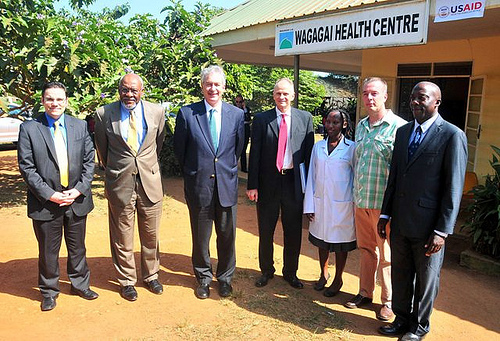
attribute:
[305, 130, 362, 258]
coat — white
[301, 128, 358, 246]
coat — white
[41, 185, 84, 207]
hands — clasped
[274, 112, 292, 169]
tie — pink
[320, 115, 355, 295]
skin — dark brown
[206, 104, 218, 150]
tie — blue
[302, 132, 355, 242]
coat — white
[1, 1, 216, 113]
trees — tropical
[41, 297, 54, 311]
shoe — black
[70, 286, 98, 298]
shoe — black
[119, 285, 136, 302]
shoe — black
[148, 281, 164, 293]
shoe — black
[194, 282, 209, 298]
shoe — black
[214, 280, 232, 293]
shoe — black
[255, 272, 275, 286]
shoe — black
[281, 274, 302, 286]
shoe — black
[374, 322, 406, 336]
shoe — black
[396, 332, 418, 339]
shoe — black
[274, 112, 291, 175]
tie — red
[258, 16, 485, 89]
sign — white, small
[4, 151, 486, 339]
road — dirt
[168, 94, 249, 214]
jacket — navy blue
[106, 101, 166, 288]
suit — brown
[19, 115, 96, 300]
suit — black